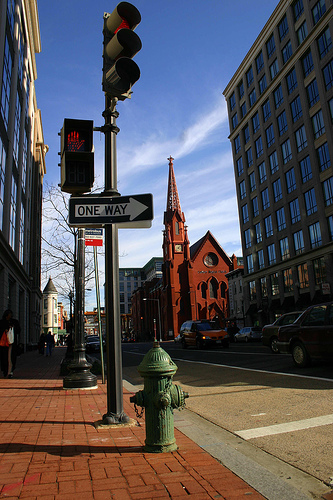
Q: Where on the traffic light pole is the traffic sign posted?
A: Middle of pole.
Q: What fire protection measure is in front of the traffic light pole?
A: Fire hydrant.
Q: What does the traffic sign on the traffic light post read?
A: ONE WAY.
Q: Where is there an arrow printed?
A: On ONE WAY traffic sign.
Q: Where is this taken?
A: A city street.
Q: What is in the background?
A: A church.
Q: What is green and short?
A: A fire hydrant.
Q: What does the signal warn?
A: Don't walk.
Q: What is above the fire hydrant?
A: A traffic signal.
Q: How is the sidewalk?
A: Made of red brick pavers.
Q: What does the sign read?
A: One Way.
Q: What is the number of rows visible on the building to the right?
A: Nine.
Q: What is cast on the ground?
A: Shadows.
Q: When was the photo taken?
A: Daytime.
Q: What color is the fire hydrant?
A: Green.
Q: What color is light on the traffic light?
A: Red.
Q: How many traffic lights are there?
A: One.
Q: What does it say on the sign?
A: One way.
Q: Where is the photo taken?
A: Out on the street.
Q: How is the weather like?
A: Nice and clear.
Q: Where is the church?
A: Background.